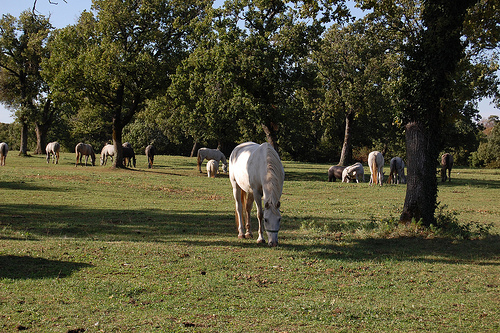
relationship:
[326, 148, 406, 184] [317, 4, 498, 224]
horses grazing around tree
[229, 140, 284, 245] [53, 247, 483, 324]
horses grazing grass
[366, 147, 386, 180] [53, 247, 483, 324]
horses grazing grass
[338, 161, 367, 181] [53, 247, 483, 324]
horses grazing grass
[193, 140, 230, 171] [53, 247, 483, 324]
horses grazing grass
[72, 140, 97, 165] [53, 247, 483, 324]
horses grazing grass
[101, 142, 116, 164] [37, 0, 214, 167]
horse behind tree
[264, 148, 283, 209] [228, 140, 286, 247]
mane on horses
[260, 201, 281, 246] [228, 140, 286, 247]
head of horses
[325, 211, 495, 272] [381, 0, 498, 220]
shadow of tree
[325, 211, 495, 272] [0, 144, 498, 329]
shadow on grass